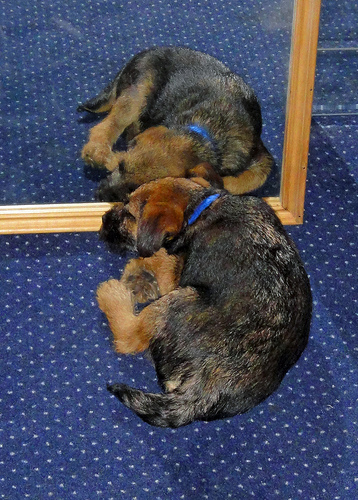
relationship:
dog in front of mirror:
[96, 176, 312, 426] [1, 1, 320, 234]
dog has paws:
[96, 176, 313, 426] [98, 247, 178, 320]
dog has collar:
[49, 36, 298, 207] [183, 191, 225, 223]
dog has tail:
[96, 176, 312, 426] [105, 376, 234, 429]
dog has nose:
[96, 176, 312, 426] [100, 214, 109, 224]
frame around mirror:
[289, 9, 315, 221] [1, 1, 320, 234]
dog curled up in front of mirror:
[96, 176, 312, 426] [1, 1, 320, 234]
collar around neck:
[188, 194, 221, 226] [174, 184, 232, 250]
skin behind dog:
[222, 145, 274, 197] [96, 176, 312, 426]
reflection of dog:
[76, 44, 275, 197] [96, 176, 312, 426]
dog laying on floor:
[96, 176, 313, 426] [0, 117, 355, 494]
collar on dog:
[187, 191, 217, 221] [96, 176, 312, 426]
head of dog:
[91, 171, 211, 263] [96, 176, 312, 426]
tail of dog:
[115, 377, 211, 420] [102, 186, 306, 416]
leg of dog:
[93, 279, 142, 360] [96, 176, 312, 426]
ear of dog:
[136, 203, 189, 257] [96, 176, 313, 426]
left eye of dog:
[122, 206, 138, 225] [96, 176, 313, 426]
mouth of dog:
[67, 186, 173, 247] [96, 176, 312, 426]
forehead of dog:
[125, 182, 147, 213] [84, 167, 332, 427]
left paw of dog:
[122, 263, 167, 301] [96, 176, 312, 426]